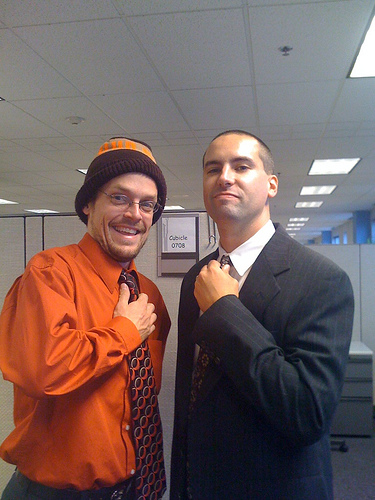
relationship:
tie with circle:
[117, 269, 167, 498] [140, 435, 150, 450]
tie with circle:
[117, 269, 167, 498] [134, 346, 144, 363]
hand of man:
[64, 273, 157, 342] [2, 132, 176, 494]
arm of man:
[30, 256, 182, 379] [0, 115, 198, 388]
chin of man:
[100, 240, 145, 265] [10, 128, 165, 493]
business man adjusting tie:
[169, 130, 354, 498] [183, 254, 229, 498]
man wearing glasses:
[2, 132, 176, 494] [96, 188, 165, 214]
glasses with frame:
[96, 188, 165, 214] [97, 187, 164, 211]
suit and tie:
[173, 222, 354, 494] [189, 349, 208, 404]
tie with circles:
[117, 269, 167, 500] [121, 273, 167, 498]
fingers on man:
[109, 276, 167, 337] [12, 135, 185, 495]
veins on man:
[135, 324, 149, 333] [19, 135, 175, 477]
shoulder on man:
[36, 242, 129, 300] [21, 117, 165, 460]